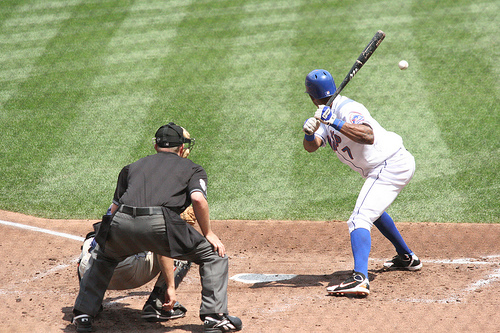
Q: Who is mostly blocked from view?
A: Catcher.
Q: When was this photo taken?
A: During a game.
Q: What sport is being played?
A: Baseball.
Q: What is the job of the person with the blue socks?
A: Hit the ball.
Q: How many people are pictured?
A: Three.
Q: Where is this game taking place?
A: Baseball field.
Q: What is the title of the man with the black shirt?
A: Umpire.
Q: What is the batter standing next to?
A: Home Plate.